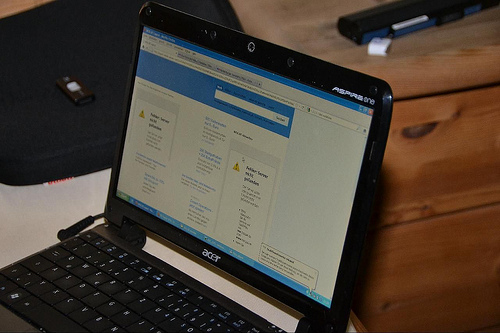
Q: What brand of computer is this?
A: Acer.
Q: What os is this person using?
A: Windows.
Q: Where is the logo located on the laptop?
A: Under the screen.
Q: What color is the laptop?
A: Black.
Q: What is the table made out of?
A: Wood.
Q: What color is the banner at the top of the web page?
A: Blue.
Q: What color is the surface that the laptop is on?
A: White.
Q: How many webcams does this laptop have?
A: One.